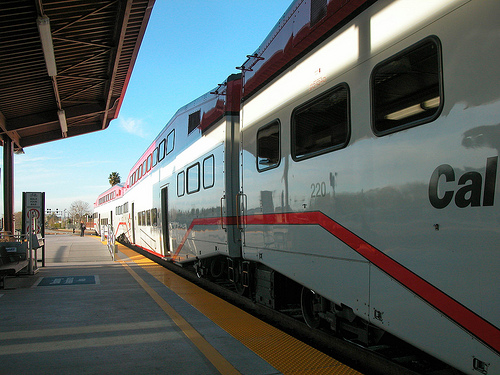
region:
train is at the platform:
[75, 150, 320, 369]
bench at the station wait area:
[3, 217, 26, 273]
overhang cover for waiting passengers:
[12, 82, 99, 157]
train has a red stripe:
[166, 194, 426, 285]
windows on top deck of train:
[115, 148, 190, 166]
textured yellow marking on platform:
[158, 287, 278, 366]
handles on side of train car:
[211, 192, 253, 237]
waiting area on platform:
[1, 88, 197, 334]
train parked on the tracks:
[68, 148, 410, 355]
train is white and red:
[147, 139, 436, 344]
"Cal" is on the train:
[404, 140, 492, 218]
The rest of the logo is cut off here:
[418, 126, 498, 247]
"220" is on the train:
[270, 165, 348, 207]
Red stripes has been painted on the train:
[241, 200, 496, 362]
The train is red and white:
[196, 39, 450, 333]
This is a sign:
[20, 172, 87, 292]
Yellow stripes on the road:
[50, 215, 315, 373]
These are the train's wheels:
[166, 229, 418, 361]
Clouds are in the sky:
[34, 126, 218, 220]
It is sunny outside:
[107, 2, 354, 243]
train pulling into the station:
[113, 60, 467, 337]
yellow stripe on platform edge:
[116, 243, 260, 361]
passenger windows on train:
[172, 152, 224, 199]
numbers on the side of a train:
[303, 176, 334, 203]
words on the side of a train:
[416, 149, 495, 212]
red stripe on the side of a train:
[243, 205, 484, 370]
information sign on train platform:
[17, 181, 54, 278]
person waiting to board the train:
[74, 213, 89, 238]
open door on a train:
[154, 178, 179, 260]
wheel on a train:
[293, 278, 326, 333]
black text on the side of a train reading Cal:
[419, 157, 499, 209]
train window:
[250, 116, 284, 172]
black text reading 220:
[303, 180, 327, 199]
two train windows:
[287, 31, 454, 163]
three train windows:
[241, 33, 462, 170]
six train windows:
[176, 31, 449, 200]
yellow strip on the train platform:
[93, 223, 359, 373]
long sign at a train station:
[23, 187, 48, 265]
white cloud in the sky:
[120, 117, 154, 140]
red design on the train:
[240, 210, 498, 349]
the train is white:
[86, 4, 487, 350]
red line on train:
[119, 176, 490, 372]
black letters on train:
[418, 111, 495, 213]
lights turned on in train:
[373, 71, 446, 129]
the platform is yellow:
[106, 225, 341, 373]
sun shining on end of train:
[73, 160, 170, 282]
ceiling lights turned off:
[27, 9, 97, 171]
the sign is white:
[20, 174, 50, 245]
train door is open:
[148, 182, 184, 273]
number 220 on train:
[285, 171, 344, 209]